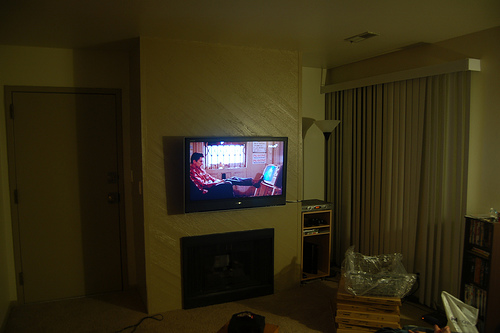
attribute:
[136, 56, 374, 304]
wall — tan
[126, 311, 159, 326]
cable — black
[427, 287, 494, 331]
bag — white, plastic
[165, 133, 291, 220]
television — square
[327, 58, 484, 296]
blinds — White 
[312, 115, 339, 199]
lamp — standing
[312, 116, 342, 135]
shade — white